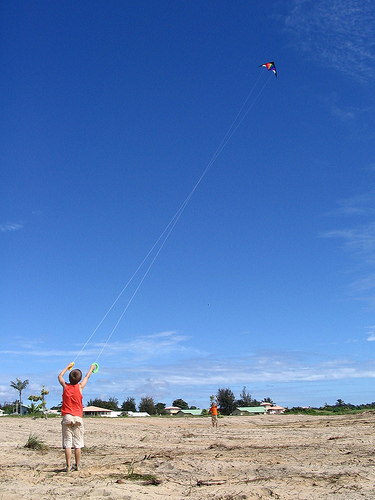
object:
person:
[58, 362, 95, 472]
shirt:
[61, 383, 83, 418]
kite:
[258, 62, 277, 79]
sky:
[61, 10, 254, 50]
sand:
[261, 435, 315, 472]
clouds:
[147, 341, 169, 358]